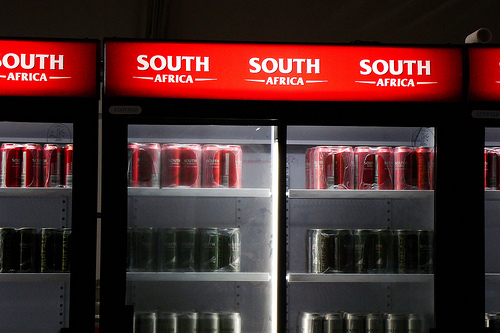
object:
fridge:
[94, 28, 471, 331]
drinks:
[160, 141, 180, 188]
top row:
[126, 123, 434, 191]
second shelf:
[129, 194, 434, 273]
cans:
[411, 146, 429, 191]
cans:
[129, 226, 157, 271]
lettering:
[132, 54, 438, 88]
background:
[102, 44, 463, 102]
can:
[219, 144, 242, 188]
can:
[179, 144, 201, 188]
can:
[200, 143, 222, 188]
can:
[219, 310, 242, 333]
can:
[176, 309, 198, 333]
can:
[298, 310, 323, 333]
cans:
[133, 310, 155, 333]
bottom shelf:
[132, 282, 431, 332]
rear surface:
[126, 126, 434, 332]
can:
[176, 226, 195, 272]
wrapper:
[128, 226, 242, 272]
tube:
[270, 122, 280, 332]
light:
[132, 136, 248, 187]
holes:
[283, 158, 291, 332]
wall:
[283, 136, 437, 332]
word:
[249, 56, 319, 73]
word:
[264, 76, 306, 86]